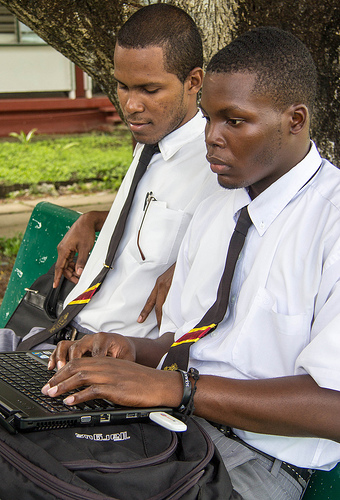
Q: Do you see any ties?
A: Yes, there is a tie.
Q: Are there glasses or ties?
A: Yes, there is a tie.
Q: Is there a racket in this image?
A: No, there are no rackets.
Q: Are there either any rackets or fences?
A: No, there are no rackets or fences.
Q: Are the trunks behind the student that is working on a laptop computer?
A: Yes, the trunks are behind the student.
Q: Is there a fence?
A: No, there are no fences.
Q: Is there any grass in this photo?
A: Yes, there is grass.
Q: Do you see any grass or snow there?
A: Yes, there is grass.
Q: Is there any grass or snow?
A: Yes, there is grass.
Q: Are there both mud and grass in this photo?
A: No, there is grass but no mud.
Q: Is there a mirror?
A: No, there are no mirrors.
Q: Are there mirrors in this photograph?
A: No, there are no mirrors.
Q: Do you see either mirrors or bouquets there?
A: No, there are no mirrors or bouquets.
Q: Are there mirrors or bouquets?
A: No, there are no mirrors or bouquets.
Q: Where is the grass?
A: The grass is on the ground.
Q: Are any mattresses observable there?
A: No, there are no mattresses.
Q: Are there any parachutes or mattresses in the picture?
A: No, there are no mattresses or parachutes.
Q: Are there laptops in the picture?
A: Yes, there is a laptop.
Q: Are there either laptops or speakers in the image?
A: Yes, there is a laptop.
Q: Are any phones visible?
A: No, there are no phones.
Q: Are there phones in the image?
A: No, there are no phones.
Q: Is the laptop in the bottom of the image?
A: Yes, the laptop is in the bottom of the image.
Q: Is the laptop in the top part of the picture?
A: No, the laptop is in the bottom of the image.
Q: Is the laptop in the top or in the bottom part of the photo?
A: The laptop is in the bottom of the image.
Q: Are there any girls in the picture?
A: No, there are no girls.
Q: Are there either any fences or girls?
A: No, there are no girls or fences.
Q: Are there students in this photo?
A: Yes, there is a student.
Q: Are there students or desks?
A: Yes, there is a student.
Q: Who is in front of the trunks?
A: The student is in front of the trunks.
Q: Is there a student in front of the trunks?
A: Yes, there is a student in front of the trunks.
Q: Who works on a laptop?
A: The student works on a laptop.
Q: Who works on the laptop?
A: The student works on a laptop.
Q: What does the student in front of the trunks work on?
A: The student works on a laptop.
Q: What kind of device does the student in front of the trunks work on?
A: The student works on a laptop.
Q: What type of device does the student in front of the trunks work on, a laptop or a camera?
A: The student works on a laptop.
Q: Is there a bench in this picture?
A: Yes, there is a bench.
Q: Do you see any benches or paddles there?
A: Yes, there is a bench.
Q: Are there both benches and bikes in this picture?
A: No, there is a bench but no bikes.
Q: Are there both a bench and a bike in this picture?
A: No, there is a bench but no bikes.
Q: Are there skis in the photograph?
A: No, there are no skis.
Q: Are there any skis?
A: No, there are no skis.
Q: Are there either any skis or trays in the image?
A: No, there are no skis or trays.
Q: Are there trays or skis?
A: No, there are no skis or trays.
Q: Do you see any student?
A: Yes, there are students.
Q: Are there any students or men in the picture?
A: Yes, there are students.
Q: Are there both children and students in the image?
A: No, there are students but no children.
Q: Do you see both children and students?
A: No, there are students but no children.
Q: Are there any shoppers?
A: No, there are no shoppers.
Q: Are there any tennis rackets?
A: No, there are no tennis rackets.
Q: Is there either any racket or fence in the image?
A: No, there are no rackets or fences.